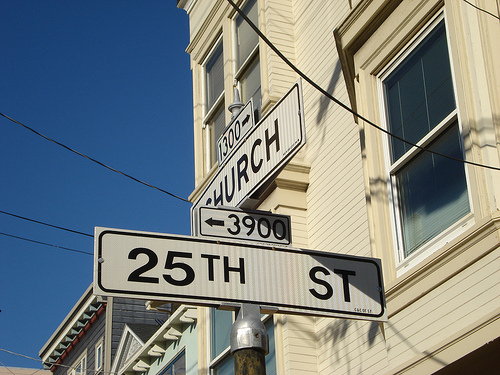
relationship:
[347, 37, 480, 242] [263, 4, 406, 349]
window on building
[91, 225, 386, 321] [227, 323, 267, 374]
address sign on pole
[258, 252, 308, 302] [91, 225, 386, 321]
grey lines on address sign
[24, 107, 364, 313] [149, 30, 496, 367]
line next to building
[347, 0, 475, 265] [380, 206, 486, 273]
window with trim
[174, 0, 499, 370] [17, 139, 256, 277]
building in background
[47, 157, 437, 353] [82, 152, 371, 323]
metal holder attached sign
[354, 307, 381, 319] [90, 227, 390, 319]
numbers in corner of sign